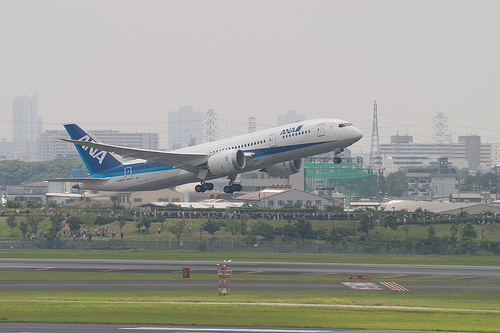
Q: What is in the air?
A: Plane.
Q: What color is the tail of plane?
A: Blue.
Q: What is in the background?
A: Buildings.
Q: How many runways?
A: 3.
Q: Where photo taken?
A: At an airport runway.